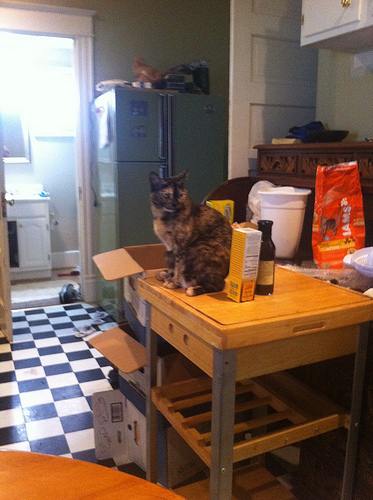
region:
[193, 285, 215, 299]
tail of a cat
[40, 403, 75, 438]
part of the floor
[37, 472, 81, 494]
top of a table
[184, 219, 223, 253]
stomach of a cat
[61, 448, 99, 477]
edge of a table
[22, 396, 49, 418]
part of a black part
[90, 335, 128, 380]
edge of a box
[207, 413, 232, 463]
part of a stand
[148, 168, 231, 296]
Cat sitting on a wooden table.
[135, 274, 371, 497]
Wooden table in the kitchen.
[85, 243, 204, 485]
Stacked cardboard boxes on the kitchen's floor.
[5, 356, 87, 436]
White and black tiles covering the floor.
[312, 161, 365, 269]
Orange bag of Iams cat food.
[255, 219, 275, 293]
Brown bottle of sauce on a wooden cart table.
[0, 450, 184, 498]
Wooden breakfast table in the kitchen.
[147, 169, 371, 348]
Black and brown cat sitting on top of wooden cart.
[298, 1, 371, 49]
White cabinet door with gold knob.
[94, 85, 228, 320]
Three door refrigerator in the kitchen.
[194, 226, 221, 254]
stomach of a cut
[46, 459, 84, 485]
top of a table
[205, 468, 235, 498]
part of a stand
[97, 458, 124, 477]
edge of the table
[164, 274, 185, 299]
part of some paws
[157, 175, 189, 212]
face of a cat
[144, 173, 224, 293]
this is a cat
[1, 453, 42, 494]
this is a table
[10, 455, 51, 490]
the table is wooden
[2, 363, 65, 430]
this is the floor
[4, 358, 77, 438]
the floor is made of tiles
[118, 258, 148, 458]
these are several boxes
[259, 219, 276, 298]
this is a bottle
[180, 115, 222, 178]
this is a fridge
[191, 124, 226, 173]
the fridge is green in color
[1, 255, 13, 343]
this is a door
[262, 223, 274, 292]
the bottle is made of glass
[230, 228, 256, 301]
this is a box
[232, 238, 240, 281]
the box is yellow in color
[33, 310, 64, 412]
this is the floor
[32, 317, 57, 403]
the floor is made of tiles